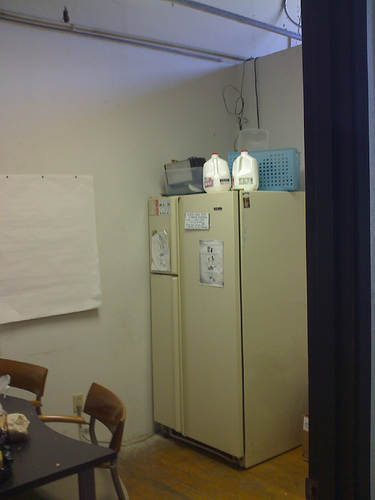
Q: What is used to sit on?
A: Chairs.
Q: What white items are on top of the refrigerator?
A: Milk cartons.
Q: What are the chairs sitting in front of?
A: A table.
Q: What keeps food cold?
A: Refrigerator.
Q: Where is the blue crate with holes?
A: Top of the refrigerator.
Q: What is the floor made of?
A: Wood.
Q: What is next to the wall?
A: Fridge.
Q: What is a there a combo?
A: Fridge and freezer.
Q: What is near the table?
A: Chair.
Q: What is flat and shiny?
A: Table.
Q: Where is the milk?
A: On fridge.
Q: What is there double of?
A: Doors.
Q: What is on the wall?
A: Board.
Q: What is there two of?
A: Wooden chairs.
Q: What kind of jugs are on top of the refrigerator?
A: Milk jugs.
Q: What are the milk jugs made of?
A: Plastic.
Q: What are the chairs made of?
A: Wood.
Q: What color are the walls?
A: White.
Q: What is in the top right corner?
A: A fridge.